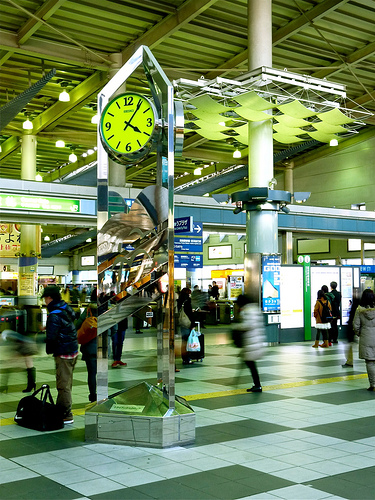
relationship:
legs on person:
[54, 355, 75, 423] [38, 284, 74, 424]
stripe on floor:
[180, 360, 361, 402] [0, 302, 373, 498]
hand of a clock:
[123, 120, 141, 133] [101, 92, 156, 161]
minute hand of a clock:
[121, 100, 143, 126] [97, 90, 167, 161]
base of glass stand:
[81, 378, 199, 450] [89, 40, 195, 447]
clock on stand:
[76, 77, 152, 149] [58, 149, 245, 419]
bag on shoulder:
[176, 297, 193, 328] [181, 297, 192, 308]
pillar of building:
[243, 1, 278, 253] [3, 1, 372, 498]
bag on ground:
[14, 386, 71, 431] [69, 446, 308, 469]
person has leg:
[230, 291, 265, 381] [239, 359, 265, 393]